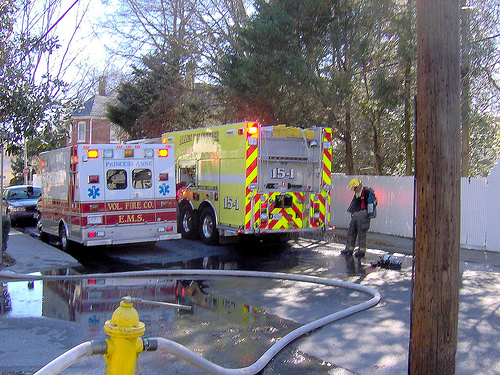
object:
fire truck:
[160, 120, 333, 246]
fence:
[328, 172, 489, 253]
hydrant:
[100, 294, 191, 374]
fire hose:
[32, 336, 106, 375]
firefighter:
[340, 177, 378, 258]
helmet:
[344, 176, 360, 191]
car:
[0, 184, 42, 228]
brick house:
[60, 74, 131, 147]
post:
[408, 0, 461, 375]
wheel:
[57, 217, 69, 252]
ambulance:
[31, 142, 185, 249]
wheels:
[193, 200, 217, 246]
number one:
[289, 167, 296, 180]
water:
[1, 250, 362, 375]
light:
[158, 147, 170, 156]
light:
[86, 149, 98, 159]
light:
[246, 126, 260, 136]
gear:
[273, 192, 293, 210]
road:
[0, 226, 499, 374]